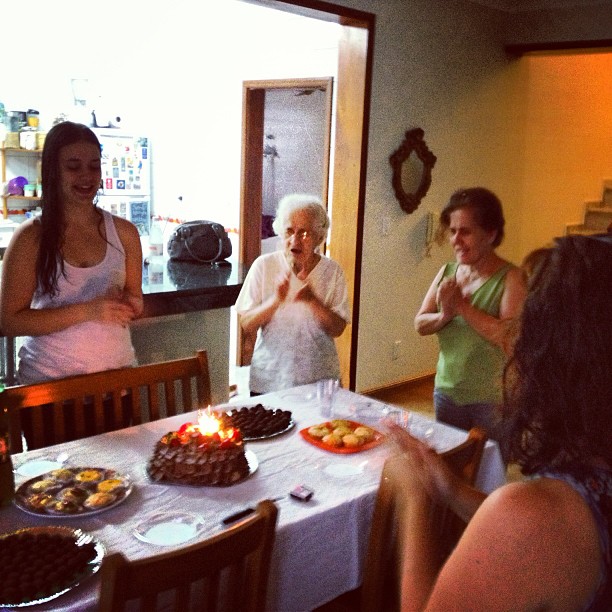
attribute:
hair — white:
[267, 188, 333, 242]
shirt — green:
[420, 245, 526, 416]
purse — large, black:
[154, 205, 251, 271]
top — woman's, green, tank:
[420, 249, 537, 415]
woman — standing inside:
[409, 172, 540, 466]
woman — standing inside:
[0, 111, 159, 409]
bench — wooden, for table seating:
[2, 340, 235, 462]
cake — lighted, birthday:
[142, 398, 261, 497]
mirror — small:
[378, 116, 455, 229]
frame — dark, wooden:
[376, 111, 443, 226]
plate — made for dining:
[10, 466, 134, 520]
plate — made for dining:
[299, 417, 388, 453]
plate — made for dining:
[217, 405, 296, 442]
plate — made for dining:
[0, 524, 106, 608]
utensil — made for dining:
[221, 493, 283, 525]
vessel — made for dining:
[316, 378, 337, 415]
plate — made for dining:
[131, 507, 205, 548]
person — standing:
[3, 122, 143, 450]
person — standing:
[236, 195, 350, 398]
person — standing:
[415, 188, 527, 471]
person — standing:
[383, 235, 607, 607]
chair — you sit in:
[99, 500, 279, 609]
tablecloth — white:
[2, 380, 502, 610]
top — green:
[430, 252, 513, 399]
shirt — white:
[240, 251, 346, 392]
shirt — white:
[231, 249, 351, 388]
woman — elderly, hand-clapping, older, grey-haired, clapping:
[236, 189, 355, 399]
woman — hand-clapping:
[413, 181, 525, 443]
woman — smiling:
[3, 117, 144, 454]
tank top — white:
[20, 206, 136, 385]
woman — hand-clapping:
[420, 179, 523, 433]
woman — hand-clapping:
[225, 189, 357, 397]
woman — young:
[12, 115, 143, 442]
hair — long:
[25, 117, 118, 299]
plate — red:
[298, 413, 387, 460]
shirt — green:
[426, 252, 518, 401]